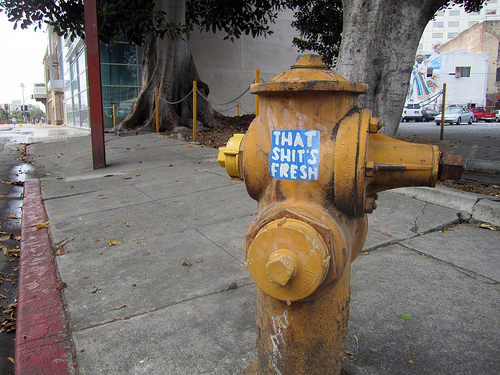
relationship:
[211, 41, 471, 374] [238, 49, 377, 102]
fire hydrant has top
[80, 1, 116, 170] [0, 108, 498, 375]
pole on area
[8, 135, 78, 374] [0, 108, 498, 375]
edge of area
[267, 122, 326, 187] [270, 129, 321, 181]
sticker has sign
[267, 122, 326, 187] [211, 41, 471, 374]
sign on fire hydrant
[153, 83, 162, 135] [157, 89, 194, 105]
post has chain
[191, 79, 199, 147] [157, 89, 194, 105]
post has chain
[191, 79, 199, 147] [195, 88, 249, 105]
post has chain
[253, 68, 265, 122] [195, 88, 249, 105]
post has chain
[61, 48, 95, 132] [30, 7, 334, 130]
window on front of building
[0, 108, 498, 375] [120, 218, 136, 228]
area has leaf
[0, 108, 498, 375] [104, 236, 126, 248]
area has leaf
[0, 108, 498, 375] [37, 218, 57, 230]
area has leaf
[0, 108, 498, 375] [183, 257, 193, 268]
area has leaf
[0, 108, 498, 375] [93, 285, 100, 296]
area has leaf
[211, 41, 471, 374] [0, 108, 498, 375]
fire hydrant on area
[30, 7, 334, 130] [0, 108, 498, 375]
building along area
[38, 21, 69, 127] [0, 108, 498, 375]
building along area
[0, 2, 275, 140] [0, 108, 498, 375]
tree near area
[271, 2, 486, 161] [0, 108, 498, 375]
tree near area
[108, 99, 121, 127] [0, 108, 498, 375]
post on area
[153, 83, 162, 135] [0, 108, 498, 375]
post on area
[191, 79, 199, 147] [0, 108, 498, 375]
post on area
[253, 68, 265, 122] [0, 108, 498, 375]
post on area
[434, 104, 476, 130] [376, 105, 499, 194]
car in lot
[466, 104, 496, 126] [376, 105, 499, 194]
truck in lot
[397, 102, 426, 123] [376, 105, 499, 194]
van in lot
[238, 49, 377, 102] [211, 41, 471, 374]
top on fire hydrant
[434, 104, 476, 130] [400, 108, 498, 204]
car in area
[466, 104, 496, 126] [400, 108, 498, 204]
car in area